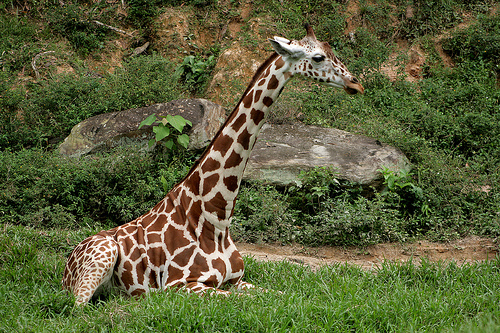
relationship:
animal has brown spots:
[64, 28, 363, 309] [292, 45, 349, 85]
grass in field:
[2, 257, 495, 331] [1, 217, 498, 331]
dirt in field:
[261, 231, 481, 268] [32, 119, 480, 274]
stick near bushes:
[93, 20, 142, 47] [1, 56, 179, 147]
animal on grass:
[64, 23, 364, 310] [1, 225, 498, 330]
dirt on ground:
[261, 231, 481, 268] [2, 0, 496, 327]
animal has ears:
[64, 23, 364, 310] [268, 35, 306, 64]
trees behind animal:
[5, 52, 193, 117] [64, 23, 364, 310]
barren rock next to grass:
[246, 120, 420, 192] [0, 0, 497, 332]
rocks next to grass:
[51, 86, 423, 218] [285, 237, 494, 300]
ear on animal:
[264, 33, 304, 61] [64, 23, 364, 310]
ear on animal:
[264, 37, 305, 61] [64, 23, 364, 310]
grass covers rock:
[3, 34, 497, 331] [58, 95, 225, 162]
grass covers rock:
[3, 34, 497, 331] [239, 122, 424, 184]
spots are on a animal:
[118, 255, 148, 290] [64, 28, 363, 309]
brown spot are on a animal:
[203, 197, 229, 217] [64, 28, 363, 309]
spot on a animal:
[196, 154, 220, 185] [61, 30, 392, 300]